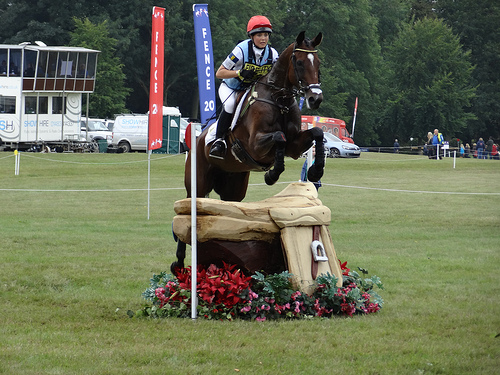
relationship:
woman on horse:
[208, 14, 277, 164] [169, 32, 326, 285]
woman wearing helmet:
[208, 14, 277, 164] [246, 14, 274, 35]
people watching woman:
[426, 128, 442, 159] [208, 14, 277, 164]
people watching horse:
[426, 128, 442, 159] [169, 32, 326, 285]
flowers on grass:
[139, 260, 383, 317] [1, 151, 499, 374]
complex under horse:
[175, 181, 347, 294] [169, 32, 326, 285]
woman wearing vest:
[208, 14, 277, 164] [223, 40, 271, 90]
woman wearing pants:
[208, 14, 277, 164] [217, 81, 241, 118]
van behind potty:
[111, 114, 192, 152] [152, 106, 181, 153]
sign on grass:
[191, 2, 217, 130] [1, 151, 499, 374]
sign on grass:
[150, 5, 163, 155] [1, 151, 499, 374]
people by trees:
[426, 128, 442, 159] [1, 0, 499, 154]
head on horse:
[280, 30, 323, 114] [169, 32, 326, 285]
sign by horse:
[191, 2, 217, 130] [169, 32, 326, 285]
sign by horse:
[150, 5, 163, 155] [169, 32, 326, 285]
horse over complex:
[169, 32, 326, 285] [175, 181, 347, 294]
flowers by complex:
[139, 260, 383, 317] [175, 181, 347, 294]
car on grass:
[319, 129, 360, 160] [1, 151, 499, 374]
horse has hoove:
[169, 32, 326, 285] [306, 166, 325, 182]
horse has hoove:
[169, 32, 326, 285] [262, 169, 279, 186]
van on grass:
[111, 114, 192, 152] [1, 151, 499, 374]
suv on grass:
[301, 114, 355, 144] [1, 151, 499, 374]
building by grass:
[1, 42, 100, 150] [1, 151, 499, 374]